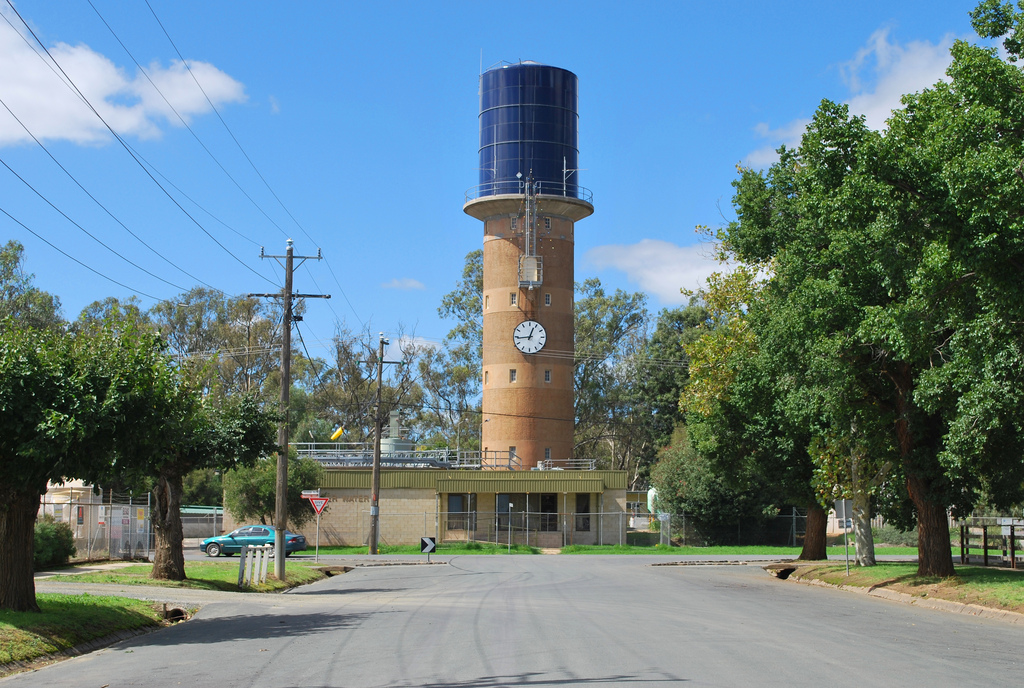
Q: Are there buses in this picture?
A: No, there are no buses.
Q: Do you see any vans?
A: No, there are no vans.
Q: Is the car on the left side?
A: Yes, the car is on the left of the image.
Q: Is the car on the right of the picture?
A: No, the car is on the left of the image.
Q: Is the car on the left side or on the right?
A: The car is on the left of the image.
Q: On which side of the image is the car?
A: The car is on the left of the image.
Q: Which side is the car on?
A: The car is on the left of the image.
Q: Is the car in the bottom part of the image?
A: Yes, the car is in the bottom of the image.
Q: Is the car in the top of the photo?
A: No, the car is in the bottom of the image.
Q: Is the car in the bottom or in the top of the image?
A: The car is in the bottom of the image.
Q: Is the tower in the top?
A: Yes, the tower is in the top of the image.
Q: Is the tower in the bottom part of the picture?
A: No, the tower is in the top of the image.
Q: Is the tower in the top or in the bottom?
A: The tower is in the top of the image.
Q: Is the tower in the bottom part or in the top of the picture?
A: The tower is in the top of the image.